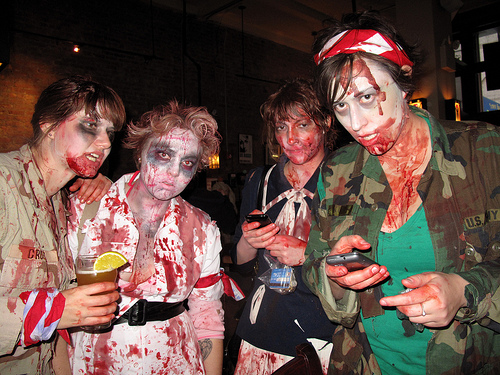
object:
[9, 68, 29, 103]
wall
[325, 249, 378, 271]
snow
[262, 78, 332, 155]
hair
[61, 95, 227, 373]
person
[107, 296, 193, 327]
belt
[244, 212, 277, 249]
cell phone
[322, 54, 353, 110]
hair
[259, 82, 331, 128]
hair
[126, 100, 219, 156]
hair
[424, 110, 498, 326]
shirt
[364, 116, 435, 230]
red stain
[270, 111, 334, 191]
red stain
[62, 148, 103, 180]
red stain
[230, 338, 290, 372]
red stain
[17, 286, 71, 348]
red stain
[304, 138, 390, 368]
green cloth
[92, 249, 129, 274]
slice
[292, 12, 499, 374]
person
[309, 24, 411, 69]
band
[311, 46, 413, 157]
head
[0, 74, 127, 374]
person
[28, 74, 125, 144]
hair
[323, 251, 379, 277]
phone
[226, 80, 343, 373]
person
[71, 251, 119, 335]
cup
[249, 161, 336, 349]
shirt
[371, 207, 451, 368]
shirt